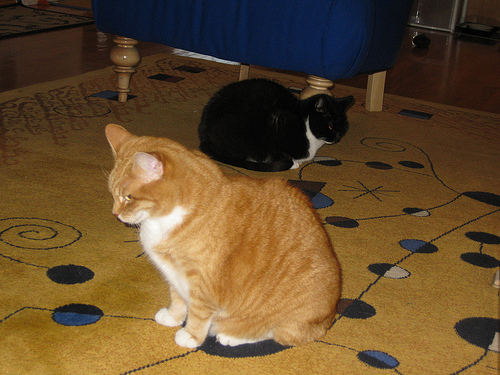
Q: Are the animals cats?
A: Yes, all the animals are cats.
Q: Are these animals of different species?
A: No, all the animals are cats.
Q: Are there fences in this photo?
A: No, there are no fences.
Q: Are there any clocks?
A: No, there are no clocks.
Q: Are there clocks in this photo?
A: No, there are no clocks.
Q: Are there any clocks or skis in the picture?
A: No, there are no clocks or skis.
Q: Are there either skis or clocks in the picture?
A: No, there are no clocks or skis.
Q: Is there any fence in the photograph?
A: No, there are no fences.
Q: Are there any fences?
A: No, there are no fences.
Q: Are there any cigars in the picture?
A: No, there are no cigars.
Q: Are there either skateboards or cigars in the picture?
A: No, there are no cigars or skateboards.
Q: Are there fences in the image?
A: No, there are no fences.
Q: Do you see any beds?
A: No, there are no beds.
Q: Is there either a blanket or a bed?
A: No, there are no beds or blankets.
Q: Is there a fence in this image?
A: No, there are no fences.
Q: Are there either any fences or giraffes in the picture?
A: No, there are no fences or giraffes.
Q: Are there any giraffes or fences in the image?
A: No, there are no fences or giraffes.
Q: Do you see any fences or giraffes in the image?
A: No, there are no fences or giraffes.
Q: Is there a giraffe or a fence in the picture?
A: No, there are no fences or giraffes.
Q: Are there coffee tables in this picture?
A: No, there are no coffee tables.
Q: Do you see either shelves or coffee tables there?
A: No, there are no coffee tables or shelves.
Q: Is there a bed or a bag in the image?
A: No, there are no beds or bags.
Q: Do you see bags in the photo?
A: No, there are no bags.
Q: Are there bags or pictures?
A: No, there are no bags or pictures.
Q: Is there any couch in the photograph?
A: Yes, there is a couch.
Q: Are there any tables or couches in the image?
A: Yes, there is a couch.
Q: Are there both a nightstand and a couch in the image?
A: No, there is a couch but no nightstands.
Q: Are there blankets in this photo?
A: No, there are no blankets.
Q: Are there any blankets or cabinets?
A: No, there are no blankets or cabinets.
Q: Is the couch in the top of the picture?
A: Yes, the couch is in the top of the image.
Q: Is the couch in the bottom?
A: No, the couch is in the top of the image.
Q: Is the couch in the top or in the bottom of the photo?
A: The couch is in the top of the image.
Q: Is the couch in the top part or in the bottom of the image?
A: The couch is in the top of the image.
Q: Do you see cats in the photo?
A: Yes, there is a cat.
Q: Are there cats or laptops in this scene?
A: Yes, there is a cat.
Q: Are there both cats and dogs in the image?
A: No, there is a cat but no dogs.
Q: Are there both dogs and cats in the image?
A: No, there is a cat but no dogs.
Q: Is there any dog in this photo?
A: No, there are no dogs.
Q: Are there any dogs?
A: No, there are no dogs.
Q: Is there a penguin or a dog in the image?
A: No, there are no dogs or penguins.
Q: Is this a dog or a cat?
A: This is a cat.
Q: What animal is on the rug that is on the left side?
A: The cat is on the rug.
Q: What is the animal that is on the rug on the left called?
A: The animal is a cat.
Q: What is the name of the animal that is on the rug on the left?
A: The animal is a cat.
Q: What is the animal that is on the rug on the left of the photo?
A: The animal is a cat.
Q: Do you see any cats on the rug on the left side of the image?
A: Yes, there is a cat on the rug.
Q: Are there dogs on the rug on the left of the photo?
A: No, there is a cat on the rug.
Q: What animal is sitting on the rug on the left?
A: The cat is sitting on the rug.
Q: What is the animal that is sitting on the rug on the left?
A: The animal is a cat.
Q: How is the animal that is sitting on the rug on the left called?
A: The animal is a cat.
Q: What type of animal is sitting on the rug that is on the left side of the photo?
A: The animal is a cat.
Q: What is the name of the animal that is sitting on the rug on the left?
A: The animal is a cat.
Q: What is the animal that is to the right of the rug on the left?
A: The animal is a cat.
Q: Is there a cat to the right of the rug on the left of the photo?
A: Yes, there is a cat to the right of the rug.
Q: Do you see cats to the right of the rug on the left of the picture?
A: Yes, there is a cat to the right of the rug.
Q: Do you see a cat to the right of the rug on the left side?
A: Yes, there is a cat to the right of the rug.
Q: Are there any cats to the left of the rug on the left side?
A: No, the cat is to the right of the rug.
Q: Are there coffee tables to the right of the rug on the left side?
A: No, there is a cat to the right of the rug.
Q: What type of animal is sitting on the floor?
A: The animal is a cat.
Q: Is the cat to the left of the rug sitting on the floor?
A: Yes, the cat is sitting on the floor.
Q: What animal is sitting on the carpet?
A: The cat is sitting on the carpet.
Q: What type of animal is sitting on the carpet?
A: The animal is a cat.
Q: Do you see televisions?
A: No, there are no televisions.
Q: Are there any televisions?
A: No, there are no televisions.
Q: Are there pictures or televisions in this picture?
A: No, there are no televisions or pictures.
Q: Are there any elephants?
A: No, there are no elephants.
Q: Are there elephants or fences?
A: No, there are no elephants or fences.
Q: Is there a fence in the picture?
A: No, there are no fences.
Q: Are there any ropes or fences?
A: No, there are no fences or ropes.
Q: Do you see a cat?
A: Yes, there is a cat.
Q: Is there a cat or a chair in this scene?
A: Yes, there is a cat.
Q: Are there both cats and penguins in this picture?
A: No, there is a cat but no penguins.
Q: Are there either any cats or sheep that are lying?
A: Yes, the cat is lying.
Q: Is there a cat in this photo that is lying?
A: Yes, there is a cat that is lying.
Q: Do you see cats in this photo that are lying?
A: Yes, there is a cat that is lying.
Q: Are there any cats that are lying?
A: Yes, there is a cat that is lying.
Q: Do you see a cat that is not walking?
A: Yes, there is a cat that is lying .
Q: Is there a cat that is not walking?
A: Yes, there is a cat that is lying.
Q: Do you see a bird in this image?
A: No, there are no birds.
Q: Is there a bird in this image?
A: No, there are no birds.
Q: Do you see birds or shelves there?
A: No, there are no birds or shelves.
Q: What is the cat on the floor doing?
A: The cat is lying.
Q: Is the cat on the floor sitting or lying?
A: The cat is lying.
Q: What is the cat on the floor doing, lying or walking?
A: The cat is lying.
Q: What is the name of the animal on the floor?
A: The animal is a cat.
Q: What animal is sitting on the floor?
A: The cat is sitting on the floor.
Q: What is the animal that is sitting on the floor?
A: The animal is a cat.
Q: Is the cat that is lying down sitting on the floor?
A: Yes, the cat is sitting on the floor.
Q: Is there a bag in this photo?
A: No, there are no bags.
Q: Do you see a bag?
A: No, there are no bags.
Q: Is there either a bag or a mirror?
A: No, there are no bags or mirrors.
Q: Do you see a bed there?
A: No, there are no beds.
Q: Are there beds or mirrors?
A: No, there are no beds or mirrors.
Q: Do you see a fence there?
A: No, there are no fences.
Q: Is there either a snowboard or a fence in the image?
A: No, there are no fences or snowboards.